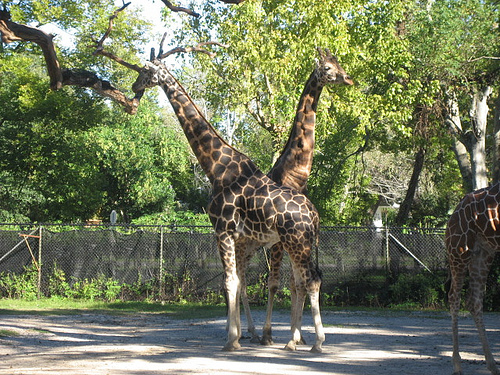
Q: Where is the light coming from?
A: Sunlight through trees.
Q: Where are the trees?
A: Behind the fence.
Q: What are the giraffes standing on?
A: Dirt.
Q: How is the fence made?
A: Chain link.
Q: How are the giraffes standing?
A: Facing away from each other.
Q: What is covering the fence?
A: Black tarp.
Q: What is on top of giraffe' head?
A: Horns.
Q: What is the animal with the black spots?
A: A giraffe.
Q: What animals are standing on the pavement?
A: Giraffes.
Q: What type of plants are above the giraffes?
A: Trees.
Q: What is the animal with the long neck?
A: A giraffe.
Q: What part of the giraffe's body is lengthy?
A: The neck.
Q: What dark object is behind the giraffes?
A: A fence.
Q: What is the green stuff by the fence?
A: Grass.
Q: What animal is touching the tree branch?
A: A giraffe.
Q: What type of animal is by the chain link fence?
A: A giraffe.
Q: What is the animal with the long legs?
A: A giraffe.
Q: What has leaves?
A: The large green tree.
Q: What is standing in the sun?
A: Two giraffes.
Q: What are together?
A: Two giraffes.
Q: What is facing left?
A: The giraffe.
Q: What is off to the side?
A: The third giraffe.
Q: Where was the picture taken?
A: Zoo.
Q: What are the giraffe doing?
A: Standing.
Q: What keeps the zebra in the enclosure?
A: Fence.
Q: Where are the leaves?
A: On the trees.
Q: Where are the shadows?
A: On the ground.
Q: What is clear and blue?
A: The sky.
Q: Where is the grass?
A: On the ground.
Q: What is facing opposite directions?
A: Two giraffes.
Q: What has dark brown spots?
A: Giraffes.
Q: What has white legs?
A: Giraffes.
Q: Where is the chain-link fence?
A: Behind giraffes.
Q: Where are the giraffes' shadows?
A: On ground.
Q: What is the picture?
A: Giraffes.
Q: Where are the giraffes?
A: Zoo.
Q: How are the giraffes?
A: Tall.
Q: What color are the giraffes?
A: Brown.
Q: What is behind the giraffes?
A: Fence.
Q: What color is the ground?
A: Gray.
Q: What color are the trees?
A: Green.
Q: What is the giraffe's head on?
A: Branch.